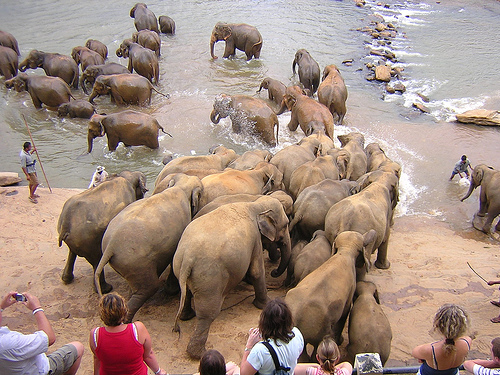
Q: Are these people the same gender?
A: No, they are both male and female.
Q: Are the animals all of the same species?
A: Yes, all the animals are elephants.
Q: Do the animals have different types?
A: No, all the animals are elephants.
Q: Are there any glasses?
A: No, there are no glasses.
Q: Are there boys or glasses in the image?
A: No, there are no glasses or boys.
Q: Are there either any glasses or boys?
A: No, there are no glasses or boys.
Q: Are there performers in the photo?
A: No, there are no performers.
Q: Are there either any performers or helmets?
A: No, there are no performers or helmets.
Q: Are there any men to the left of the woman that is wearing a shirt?
A: Yes, there is a man to the left of the woman.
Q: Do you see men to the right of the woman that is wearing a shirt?
A: No, the man is to the left of the woman.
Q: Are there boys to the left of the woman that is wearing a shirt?
A: No, there is a man to the left of the woman.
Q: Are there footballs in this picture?
A: No, there are no footballs.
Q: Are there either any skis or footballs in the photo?
A: No, there are no footballs or skis.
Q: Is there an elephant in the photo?
A: Yes, there is an elephant.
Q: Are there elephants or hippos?
A: Yes, there is an elephant.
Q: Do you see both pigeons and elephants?
A: No, there is an elephant but no pigeons.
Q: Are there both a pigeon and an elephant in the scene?
A: No, there is an elephant but no pigeons.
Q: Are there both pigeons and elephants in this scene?
A: No, there is an elephant but no pigeons.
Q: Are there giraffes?
A: No, there are no giraffes.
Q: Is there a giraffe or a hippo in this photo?
A: No, there are no giraffes or hippoes.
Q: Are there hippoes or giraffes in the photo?
A: No, there are no giraffes or hippoes.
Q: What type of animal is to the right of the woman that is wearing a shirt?
A: The animal is an elephant.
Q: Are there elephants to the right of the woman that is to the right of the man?
A: Yes, there is an elephant to the right of the woman.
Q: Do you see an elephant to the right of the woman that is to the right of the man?
A: Yes, there is an elephant to the right of the woman.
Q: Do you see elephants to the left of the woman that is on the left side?
A: No, the elephant is to the right of the woman.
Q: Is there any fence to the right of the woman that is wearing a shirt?
A: No, there is an elephant to the right of the woman.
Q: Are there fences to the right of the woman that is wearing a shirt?
A: No, there is an elephant to the right of the woman.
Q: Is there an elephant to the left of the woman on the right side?
A: Yes, there is an elephant to the left of the woman.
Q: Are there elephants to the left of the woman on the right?
A: Yes, there is an elephant to the left of the woman.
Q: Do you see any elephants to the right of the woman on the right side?
A: No, the elephant is to the left of the woman.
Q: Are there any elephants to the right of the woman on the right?
A: No, the elephant is to the left of the woman.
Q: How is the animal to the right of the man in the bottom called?
A: The animal is an elephant.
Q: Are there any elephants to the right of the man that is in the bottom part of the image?
A: Yes, there is an elephant to the right of the man.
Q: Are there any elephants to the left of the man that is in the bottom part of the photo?
A: No, the elephant is to the right of the man.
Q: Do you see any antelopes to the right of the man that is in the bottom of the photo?
A: No, there is an elephant to the right of the man.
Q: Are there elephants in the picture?
A: Yes, there is an elephant.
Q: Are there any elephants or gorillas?
A: Yes, there is an elephant.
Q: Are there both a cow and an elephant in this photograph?
A: No, there is an elephant but no cows.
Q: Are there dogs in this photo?
A: No, there are no dogs.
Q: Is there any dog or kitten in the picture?
A: No, there are no dogs or kittens.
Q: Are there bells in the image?
A: No, there are no bells.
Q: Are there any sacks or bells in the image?
A: No, there are no bells or sacks.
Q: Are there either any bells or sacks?
A: No, there are no bells or sacks.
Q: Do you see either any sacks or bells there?
A: No, there are no bells or sacks.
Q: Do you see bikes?
A: No, there are no bikes.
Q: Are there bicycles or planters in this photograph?
A: No, there are no bicycles or planters.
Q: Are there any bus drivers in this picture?
A: No, there are no bus drivers.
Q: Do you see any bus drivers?
A: No, there are no bus drivers.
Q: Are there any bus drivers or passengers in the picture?
A: No, there are no bus drivers or passengers.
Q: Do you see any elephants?
A: Yes, there are elephants.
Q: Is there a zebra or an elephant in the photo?
A: Yes, there are elephants.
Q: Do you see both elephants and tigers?
A: No, there are elephants but no tigers.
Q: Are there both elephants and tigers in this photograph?
A: No, there are elephants but no tigers.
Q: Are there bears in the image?
A: No, there are no bears.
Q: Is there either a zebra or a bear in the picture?
A: No, there are no bears or zebras.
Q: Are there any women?
A: Yes, there is a woman.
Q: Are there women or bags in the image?
A: Yes, there is a woman.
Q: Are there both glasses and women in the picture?
A: No, there is a woman but no glasses.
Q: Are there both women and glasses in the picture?
A: No, there is a woman but no glasses.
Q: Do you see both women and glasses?
A: No, there is a woman but no glasses.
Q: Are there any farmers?
A: No, there are no farmers.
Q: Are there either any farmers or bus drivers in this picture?
A: No, there are no farmers or bus drivers.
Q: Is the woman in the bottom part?
A: Yes, the woman is in the bottom of the image.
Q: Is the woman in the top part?
A: No, the woman is in the bottom of the image.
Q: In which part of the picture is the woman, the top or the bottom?
A: The woman is in the bottom of the image.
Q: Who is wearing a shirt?
A: The woman is wearing a shirt.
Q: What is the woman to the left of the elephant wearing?
A: The woman is wearing a shirt.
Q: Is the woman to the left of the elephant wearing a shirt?
A: Yes, the woman is wearing a shirt.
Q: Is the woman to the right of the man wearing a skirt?
A: No, the woman is wearing a shirt.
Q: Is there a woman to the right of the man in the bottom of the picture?
A: Yes, there is a woman to the right of the man.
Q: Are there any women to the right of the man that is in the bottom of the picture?
A: Yes, there is a woman to the right of the man.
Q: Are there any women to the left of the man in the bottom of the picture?
A: No, the woman is to the right of the man.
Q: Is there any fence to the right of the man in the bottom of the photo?
A: No, there is a woman to the right of the man.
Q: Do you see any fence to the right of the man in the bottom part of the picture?
A: No, there is a woman to the right of the man.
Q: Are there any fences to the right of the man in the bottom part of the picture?
A: No, there is a woman to the right of the man.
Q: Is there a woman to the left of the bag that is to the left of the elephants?
A: Yes, there is a woman to the left of the bag.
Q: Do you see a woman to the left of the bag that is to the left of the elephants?
A: Yes, there is a woman to the left of the bag.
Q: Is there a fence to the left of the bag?
A: No, there is a woman to the left of the bag.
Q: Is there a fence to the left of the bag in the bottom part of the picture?
A: No, there is a woman to the left of the bag.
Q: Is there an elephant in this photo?
A: Yes, there is an elephant.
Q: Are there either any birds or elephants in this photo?
A: Yes, there is an elephant.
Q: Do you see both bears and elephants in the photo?
A: No, there is an elephant but no bears.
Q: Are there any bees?
A: No, there are no bees.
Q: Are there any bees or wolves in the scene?
A: No, there are no bees or wolves.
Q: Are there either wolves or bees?
A: No, there are no bees or wolves.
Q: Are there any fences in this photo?
A: No, there are no fences.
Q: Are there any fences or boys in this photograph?
A: No, there are no fences or boys.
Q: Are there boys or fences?
A: No, there are no fences or boys.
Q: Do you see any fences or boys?
A: No, there are no fences or boys.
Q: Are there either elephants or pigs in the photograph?
A: Yes, there are elephants.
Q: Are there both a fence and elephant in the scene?
A: No, there are elephants but no fences.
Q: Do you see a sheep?
A: No, there is no sheep.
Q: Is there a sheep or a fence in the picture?
A: No, there are no sheep or fences.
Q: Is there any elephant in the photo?
A: Yes, there are elephants.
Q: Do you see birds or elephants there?
A: Yes, there are elephants.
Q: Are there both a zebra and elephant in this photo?
A: No, there are elephants but no zebras.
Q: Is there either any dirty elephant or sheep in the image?
A: Yes, there are dirty elephants.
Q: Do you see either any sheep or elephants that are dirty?
A: Yes, the elephants are dirty.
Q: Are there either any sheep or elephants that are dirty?
A: Yes, the elephants are dirty.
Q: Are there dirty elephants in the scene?
A: Yes, there are dirty elephants.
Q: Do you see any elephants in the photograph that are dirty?
A: Yes, there are elephants that are dirty.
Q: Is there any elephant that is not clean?
A: Yes, there are dirty elephants.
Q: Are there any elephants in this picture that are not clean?
A: Yes, there are dirty elephants.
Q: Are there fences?
A: No, there are no fences.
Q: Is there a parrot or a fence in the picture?
A: No, there are no fences or parrots.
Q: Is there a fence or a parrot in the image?
A: No, there are no fences or parrots.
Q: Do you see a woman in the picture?
A: Yes, there is a woman.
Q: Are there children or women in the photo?
A: Yes, there is a woman.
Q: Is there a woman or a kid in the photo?
A: Yes, there is a woman.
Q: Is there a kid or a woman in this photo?
A: Yes, there is a woman.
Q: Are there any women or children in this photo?
A: Yes, there is a woman.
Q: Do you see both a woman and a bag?
A: Yes, there are both a woman and a bag.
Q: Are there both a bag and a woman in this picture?
A: Yes, there are both a woman and a bag.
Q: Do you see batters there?
A: No, there are no batters.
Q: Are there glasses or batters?
A: No, there are no batters or glasses.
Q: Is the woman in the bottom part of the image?
A: Yes, the woman is in the bottom of the image.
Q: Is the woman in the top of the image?
A: No, the woman is in the bottom of the image.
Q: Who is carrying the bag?
A: The woman is carrying the bag.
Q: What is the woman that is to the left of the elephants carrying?
A: The woman is carrying a bag.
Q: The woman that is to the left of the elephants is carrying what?
A: The woman is carrying a bag.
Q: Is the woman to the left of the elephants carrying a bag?
A: Yes, the woman is carrying a bag.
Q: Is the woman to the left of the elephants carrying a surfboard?
A: No, the woman is carrying a bag.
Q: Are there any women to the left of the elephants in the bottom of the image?
A: Yes, there is a woman to the left of the elephants.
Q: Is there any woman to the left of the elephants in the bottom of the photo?
A: Yes, there is a woman to the left of the elephants.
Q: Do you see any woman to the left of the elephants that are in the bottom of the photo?
A: Yes, there is a woman to the left of the elephants.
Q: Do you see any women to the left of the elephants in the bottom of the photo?
A: Yes, there is a woman to the left of the elephants.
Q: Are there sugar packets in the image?
A: No, there are no sugar packets.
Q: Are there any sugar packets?
A: No, there are no sugar packets.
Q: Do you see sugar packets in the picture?
A: No, there are no sugar packets.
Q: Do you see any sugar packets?
A: No, there are no sugar packets.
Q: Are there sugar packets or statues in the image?
A: No, there are no sugar packets or statues.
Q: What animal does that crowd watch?
A: The crowd watches the elephants.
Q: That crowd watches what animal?
A: The crowd watches the elephants.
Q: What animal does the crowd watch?
A: The crowd watches the elephants.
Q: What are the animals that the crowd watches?
A: The animals are elephants.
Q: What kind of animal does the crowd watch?
A: The crowd watches the elephants.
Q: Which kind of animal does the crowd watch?
A: The crowd watches the elephants.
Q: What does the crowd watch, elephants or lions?
A: The crowd watches elephants.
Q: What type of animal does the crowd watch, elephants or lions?
A: The crowd watches elephants.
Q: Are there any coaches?
A: No, there are no coaches.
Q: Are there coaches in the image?
A: No, there are no coaches.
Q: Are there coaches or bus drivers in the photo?
A: No, there are no coaches or bus drivers.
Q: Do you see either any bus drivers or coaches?
A: No, there are no coaches or bus drivers.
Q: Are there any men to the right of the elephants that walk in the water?
A: Yes, there is a man to the right of the elephants.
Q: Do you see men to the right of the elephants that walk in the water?
A: Yes, there is a man to the right of the elephants.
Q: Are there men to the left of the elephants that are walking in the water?
A: No, the man is to the right of the elephants.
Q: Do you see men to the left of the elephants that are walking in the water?
A: No, the man is to the right of the elephants.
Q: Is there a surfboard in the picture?
A: No, there are no surfboards.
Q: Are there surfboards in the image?
A: No, there are no surfboards.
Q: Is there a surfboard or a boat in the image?
A: No, there are no surfboards or boats.